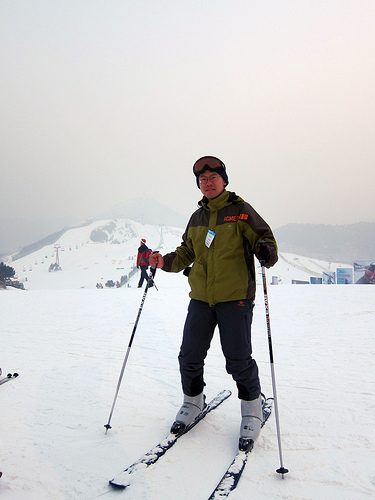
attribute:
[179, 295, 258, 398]
pants — blue, black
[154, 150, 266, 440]
man — skier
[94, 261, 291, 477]
poles — ski poles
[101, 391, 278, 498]
skis — black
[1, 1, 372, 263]
sky — blue, cloudy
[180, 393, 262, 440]
boots — grey, gray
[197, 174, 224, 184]
glasses — wire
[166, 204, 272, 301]
jacket — green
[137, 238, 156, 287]
person — walking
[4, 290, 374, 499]
ground — covered, deep, white, bright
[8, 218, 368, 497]
mountain — covered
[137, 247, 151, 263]
jacket — red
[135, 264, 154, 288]
pants — black